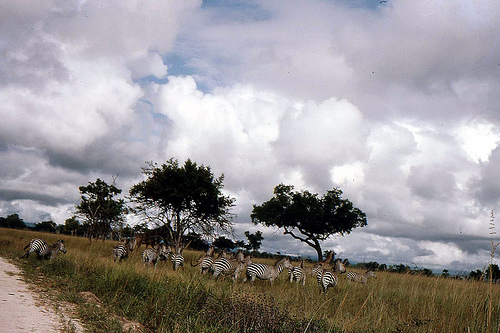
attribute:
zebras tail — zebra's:
[21, 237, 35, 248]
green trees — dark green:
[75, 180, 124, 245]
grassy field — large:
[0, 227, 499, 332]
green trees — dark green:
[118, 158, 238, 251]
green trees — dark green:
[252, 182, 364, 264]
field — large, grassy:
[1, 230, 499, 329]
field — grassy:
[90, 252, 260, 332]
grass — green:
[375, 261, 415, 296]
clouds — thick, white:
[370, 130, 465, 262]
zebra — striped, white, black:
[310, 254, 352, 294]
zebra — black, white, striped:
[20, 235, 70, 260]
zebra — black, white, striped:
[110, 240, 133, 264]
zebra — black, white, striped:
[207, 248, 246, 280]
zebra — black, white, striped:
[241, 254, 295, 286]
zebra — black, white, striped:
[313, 259, 347, 291]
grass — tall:
[176, 273, 401, 328]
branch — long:
[265, 185, 355, 242]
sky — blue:
[1, 1, 498, 272]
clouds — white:
[269, 29, 402, 128]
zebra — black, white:
[247, 258, 294, 283]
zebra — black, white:
[317, 261, 347, 292]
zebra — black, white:
[289, 259, 304, 284]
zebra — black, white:
[169, 247, 184, 267]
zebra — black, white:
[347, 268, 377, 285]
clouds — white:
[277, 97, 363, 161]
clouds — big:
[0, 1, 496, 274]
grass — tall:
[325, 281, 446, 321]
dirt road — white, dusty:
[0, 250, 83, 330]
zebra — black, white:
[18, 233, 70, 266]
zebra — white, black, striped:
[240, 256, 293, 286]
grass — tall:
[2, 227, 497, 331]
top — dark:
[251, 183, 371, 240]